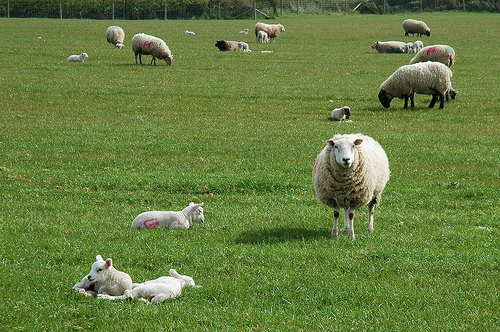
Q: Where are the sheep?
A: In a grassy field.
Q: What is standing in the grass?
A: A sheep.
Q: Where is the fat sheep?
A: In the field.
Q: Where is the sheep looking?
A: Towards the camera.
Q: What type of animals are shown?
A: Sheep.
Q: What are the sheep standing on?
A: Grass.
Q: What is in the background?
A: A fence.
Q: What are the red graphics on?
A: Side of the sheep.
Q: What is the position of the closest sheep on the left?
A: Laying.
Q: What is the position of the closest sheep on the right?
A: Standing.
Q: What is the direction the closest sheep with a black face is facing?
A: Left.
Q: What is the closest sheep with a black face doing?
A: Eating.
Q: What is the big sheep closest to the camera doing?
A: Looking at the camera.